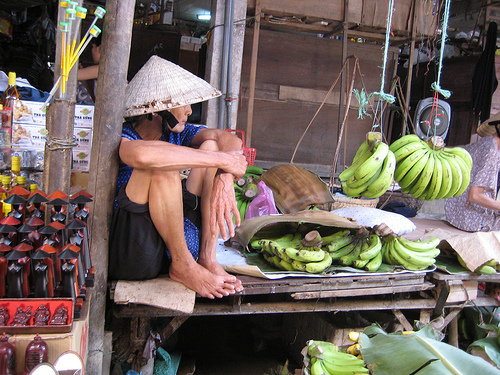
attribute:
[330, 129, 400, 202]
bananas — bunch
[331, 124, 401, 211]
bananas — bunch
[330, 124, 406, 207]
bananas — bunch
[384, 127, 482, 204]
leaf — banana, green, large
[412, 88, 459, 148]
fan — electric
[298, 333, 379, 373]
banana — green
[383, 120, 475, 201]
bananas — hanging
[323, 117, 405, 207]
bananas — unripe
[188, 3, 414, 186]
wall — wood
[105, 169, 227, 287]
outfit — black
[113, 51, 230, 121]
hat — bamboo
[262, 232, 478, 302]
bananas — green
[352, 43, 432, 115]
rope — green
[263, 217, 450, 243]
bananas — green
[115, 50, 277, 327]
man — seated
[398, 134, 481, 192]
bananas — green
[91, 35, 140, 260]
post — wooden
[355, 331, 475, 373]
leaf — green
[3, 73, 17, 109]
bottle — glass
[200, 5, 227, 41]
light — small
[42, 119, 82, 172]
rope — tied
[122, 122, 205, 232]
skin — light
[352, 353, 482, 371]
leaf — green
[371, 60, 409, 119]
rope — blue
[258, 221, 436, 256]
bananas — green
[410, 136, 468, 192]
bananas — green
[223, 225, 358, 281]
bananas — green